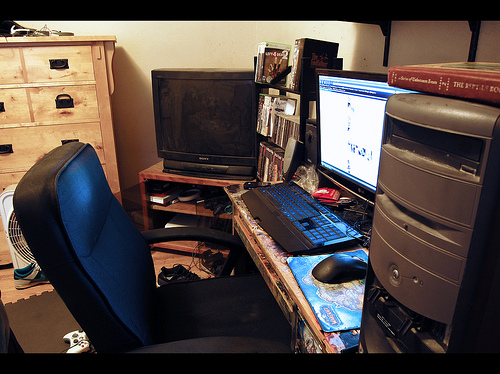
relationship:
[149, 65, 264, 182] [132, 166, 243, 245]
television on stand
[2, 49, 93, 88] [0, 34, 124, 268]
drawers on dresser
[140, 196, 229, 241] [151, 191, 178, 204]
rack with games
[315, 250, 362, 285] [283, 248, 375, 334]
mouse on mouse pad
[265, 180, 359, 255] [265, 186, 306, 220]
keyboard with keys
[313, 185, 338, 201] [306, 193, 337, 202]
book with spine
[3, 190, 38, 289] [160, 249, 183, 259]
fan sits floor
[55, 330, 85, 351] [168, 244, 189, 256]
control sits floor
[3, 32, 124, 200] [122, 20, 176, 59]
dresser against wall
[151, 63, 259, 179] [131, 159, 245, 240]
television on stand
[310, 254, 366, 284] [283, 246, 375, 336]
mouse on mouse pad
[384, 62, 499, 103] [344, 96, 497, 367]
book on top of computer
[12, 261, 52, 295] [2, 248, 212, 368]
sneaker on floor